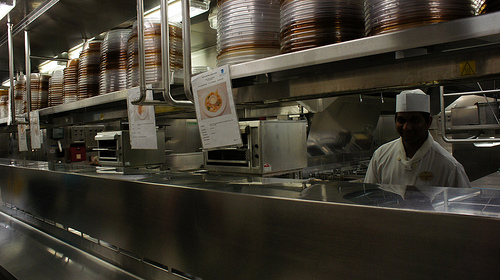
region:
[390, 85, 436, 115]
the hat is white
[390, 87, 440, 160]
the hat is on head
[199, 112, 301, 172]
microwave is silver color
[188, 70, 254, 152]
the sign is hanging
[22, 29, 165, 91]
the plates are stacked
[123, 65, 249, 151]
the signs are white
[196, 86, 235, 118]
picture on the sign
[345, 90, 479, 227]
man is behind counter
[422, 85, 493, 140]
shelf behind the man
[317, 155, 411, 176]
stove behind the man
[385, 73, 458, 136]
head of a person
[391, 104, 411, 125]
eye of a person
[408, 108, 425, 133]
eye of a person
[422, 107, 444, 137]
an ear of a person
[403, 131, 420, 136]
mouth of a person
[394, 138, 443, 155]
neck of a person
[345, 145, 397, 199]
an arm of a person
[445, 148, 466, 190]
arm of a person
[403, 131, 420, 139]
a mouth of a person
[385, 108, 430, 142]
face of a person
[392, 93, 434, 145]
a cook wearing a paper hat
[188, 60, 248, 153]
a menu item stuck to a shelf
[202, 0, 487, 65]
stainless steel shelf with items on it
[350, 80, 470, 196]
a cook in the kitchen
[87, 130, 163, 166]
a stainless steel oven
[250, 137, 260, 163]
two black knob controls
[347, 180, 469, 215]
reflection on stainless steel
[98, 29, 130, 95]
containers nested in each other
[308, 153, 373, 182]
the top of fry vats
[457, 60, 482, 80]
a triangle on stainless steel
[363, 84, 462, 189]
one man wearing white shirt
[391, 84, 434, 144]
one man wearing white chef cap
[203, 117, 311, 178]
one shiny metal kitchen oven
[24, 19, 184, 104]
several stacks of plastic lids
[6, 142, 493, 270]
long section of stainless steel counter top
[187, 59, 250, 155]
laminated rectangular white paper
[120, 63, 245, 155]
two hanging rectangular pieces of paper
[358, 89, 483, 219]
one kitchen worker behind stainless steel counter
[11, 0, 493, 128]
row of stainless steel shelving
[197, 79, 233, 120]
picture of round white plate of food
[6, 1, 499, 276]
the commercial kitchen is stainless steel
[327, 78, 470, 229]
a man is prepping for the day's meals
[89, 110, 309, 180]
commercial microwaves are in the kitchen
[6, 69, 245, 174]
menu instructions are hanging from a shelf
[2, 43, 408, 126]
stacks of plates are on a shelf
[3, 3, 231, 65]
lights are hanging from the ceiling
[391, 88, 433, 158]
the man has a white hat on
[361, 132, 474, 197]
the cook has a white shirt on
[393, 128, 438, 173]
a white scarf is around the chef's neck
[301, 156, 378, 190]
frying cookers are behind the chef